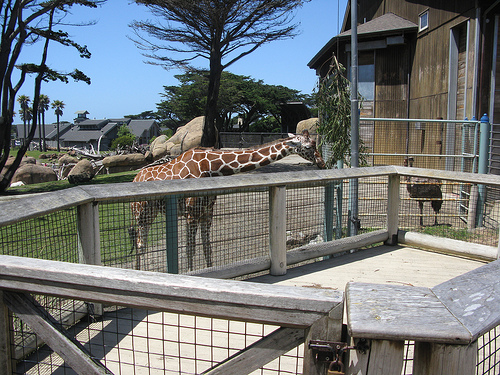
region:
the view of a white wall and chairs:
[208, 81, 241, 103]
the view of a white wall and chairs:
[264, 258, 270, 278]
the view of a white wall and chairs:
[273, 301, 299, 366]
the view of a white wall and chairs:
[273, 268, 300, 330]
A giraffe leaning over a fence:
[131, 133, 331, 262]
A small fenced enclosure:
[2, 163, 499, 374]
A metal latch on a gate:
[307, 338, 367, 371]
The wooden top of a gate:
[3, 250, 343, 326]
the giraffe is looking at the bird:
[133, 130, 443, 275]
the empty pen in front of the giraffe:
[1, 127, 498, 374]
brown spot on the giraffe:
[197, 158, 212, 173]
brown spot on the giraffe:
[219, 150, 236, 163]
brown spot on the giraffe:
[226, 160, 239, 169]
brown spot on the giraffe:
[235, 150, 252, 165]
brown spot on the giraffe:
[272, 143, 284, 150]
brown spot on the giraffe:
[182, 160, 201, 179]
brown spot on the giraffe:
[205, 151, 220, 162]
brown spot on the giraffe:
[191, 148, 206, 162]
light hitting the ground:
[353, 230, 438, 286]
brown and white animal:
[79, 130, 265, 236]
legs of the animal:
[93, 190, 239, 301]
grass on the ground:
[92, 204, 147, 256]